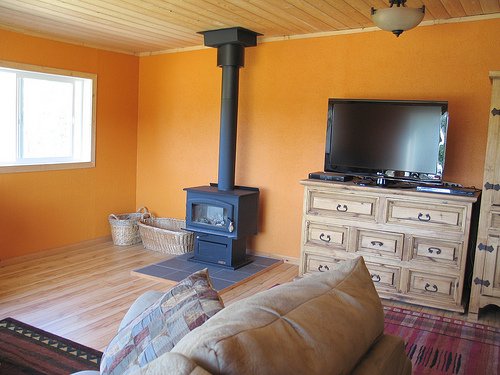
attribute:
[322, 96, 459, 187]
tv — black, flat screen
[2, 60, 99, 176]
window — rectangle-shaped, white, open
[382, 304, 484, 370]
rug — large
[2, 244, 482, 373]
floor — light, brown, hardwood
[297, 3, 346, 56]
panel — wood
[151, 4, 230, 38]
panel — wood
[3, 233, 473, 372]
floor — wooden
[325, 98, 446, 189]
flat screen tv — black, large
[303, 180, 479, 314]
dresser — light brown, wooden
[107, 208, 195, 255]
firewood in baskets — brown, wicker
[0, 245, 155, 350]
floor of wood — light, tan, wooden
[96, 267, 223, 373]
patchwork — multicolored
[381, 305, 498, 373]
black and red — woven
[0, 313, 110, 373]
in front of couch — woven, red, black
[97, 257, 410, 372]
couch — brown, tan, large, colored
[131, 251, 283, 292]
stone tiles — fireproof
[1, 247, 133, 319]
floor — wooden